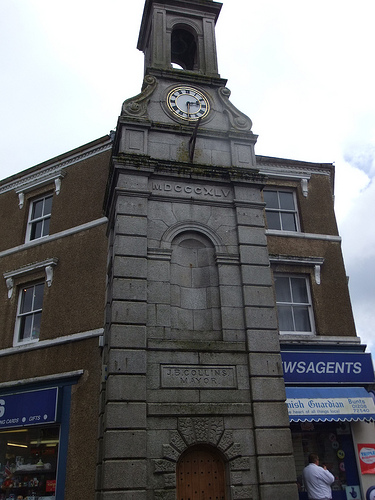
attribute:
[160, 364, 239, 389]
stone — engraved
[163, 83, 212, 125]
clock — gold-trimmed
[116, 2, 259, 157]
clock tower — stone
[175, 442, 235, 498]
door — recessed, wooden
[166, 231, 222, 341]
arch — recessed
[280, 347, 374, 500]
shop — open, newsagents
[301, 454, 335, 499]
man — standing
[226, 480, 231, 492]
bolts — black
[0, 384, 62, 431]
sign — blue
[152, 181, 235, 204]
roman numerals — stone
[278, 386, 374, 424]
awning — blue, white